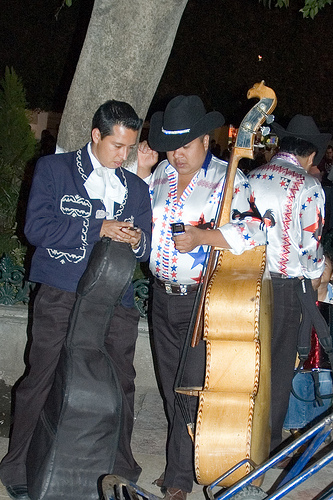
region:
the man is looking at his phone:
[165, 218, 189, 242]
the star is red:
[299, 208, 326, 234]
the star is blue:
[191, 249, 211, 268]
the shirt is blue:
[50, 169, 71, 188]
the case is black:
[83, 311, 105, 348]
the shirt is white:
[195, 191, 208, 213]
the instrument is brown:
[221, 283, 240, 320]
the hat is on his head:
[170, 107, 209, 151]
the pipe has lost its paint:
[279, 439, 310, 452]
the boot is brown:
[160, 475, 182, 498]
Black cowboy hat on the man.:
[116, 75, 330, 229]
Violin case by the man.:
[180, 227, 299, 499]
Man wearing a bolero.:
[32, 121, 220, 336]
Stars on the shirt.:
[126, 148, 288, 305]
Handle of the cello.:
[228, 77, 308, 212]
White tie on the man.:
[73, 150, 149, 227]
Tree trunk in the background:
[53, 15, 285, 217]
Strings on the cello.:
[173, 288, 313, 433]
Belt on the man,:
[142, 261, 233, 309]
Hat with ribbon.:
[129, 87, 235, 173]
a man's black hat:
[146, 92, 221, 153]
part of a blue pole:
[205, 413, 332, 497]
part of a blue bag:
[284, 355, 330, 431]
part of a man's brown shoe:
[158, 480, 184, 498]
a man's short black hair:
[89, 99, 143, 146]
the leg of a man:
[0, 285, 79, 489]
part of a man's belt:
[151, 278, 198, 297]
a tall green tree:
[0, 67, 37, 262]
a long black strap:
[298, 277, 331, 362]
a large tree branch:
[47, 0, 191, 176]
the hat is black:
[143, 96, 249, 177]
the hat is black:
[120, 66, 230, 168]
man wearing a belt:
[133, 269, 202, 299]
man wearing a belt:
[138, 264, 231, 317]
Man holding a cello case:
[22, 232, 129, 498]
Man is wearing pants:
[0, 279, 145, 487]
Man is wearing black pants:
[2, 281, 142, 493]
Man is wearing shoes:
[1, 479, 34, 498]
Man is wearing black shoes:
[3, 479, 32, 498]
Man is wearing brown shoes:
[152, 470, 191, 499]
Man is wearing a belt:
[150, 271, 209, 295]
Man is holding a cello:
[172, 77, 284, 488]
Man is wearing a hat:
[144, 91, 228, 154]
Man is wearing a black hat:
[147, 92, 226, 152]